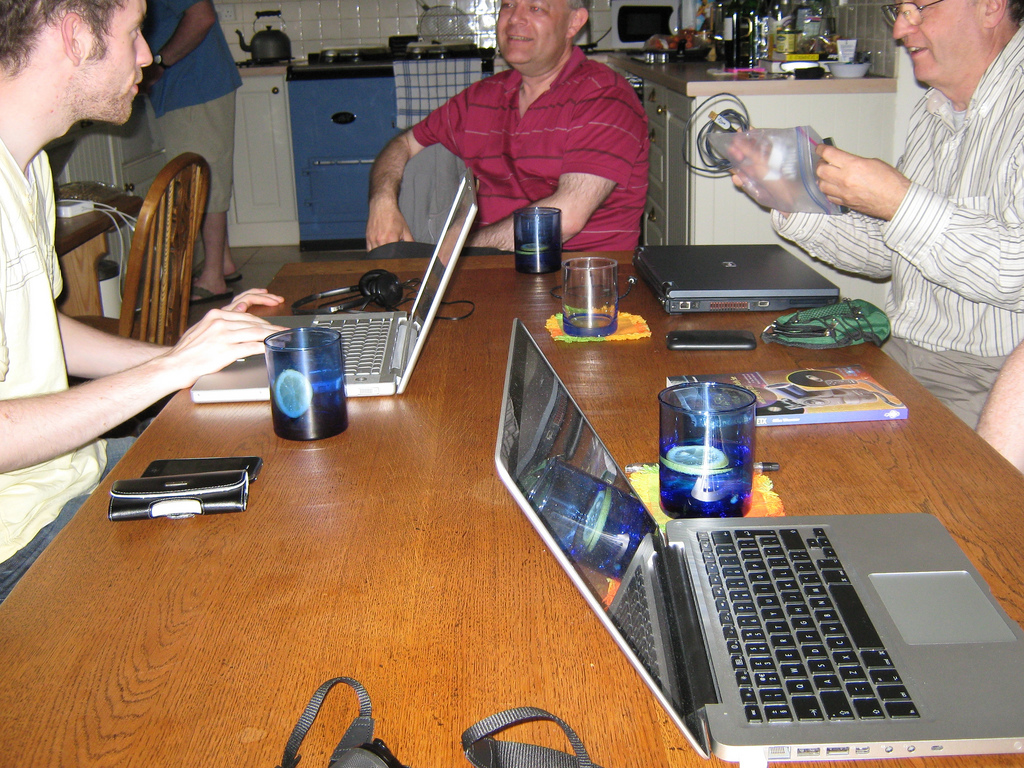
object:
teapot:
[227, 13, 306, 77]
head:
[2, 2, 152, 124]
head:
[496, 2, 592, 67]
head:
[889, 0, 1021, 84]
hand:
[169, 307, 290, 389]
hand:
[206, 284, 283, 314]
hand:
[808, 138, 906, 221]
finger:
[238, 343, 268, 356]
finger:
[246, 289, 282, 311]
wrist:
[154, 349, 206, 389]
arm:
[2, 354, 180, 473]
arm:
[57, 310, 178, 379]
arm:
[364, 95, 470, 250]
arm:
[465, 91, 637, 251]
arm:
[884, 130, 1019, 308]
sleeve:
[882, 178, 1021, 315]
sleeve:
[559, 92, 620, 187]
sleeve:
[408, 85, 482, 149]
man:
[2, 0, 297, 599]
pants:
[879, 331, 1010, 430]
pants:
[2, 495, 95, 597]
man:
[729, 2, 1020, 434]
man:
[367, 2, 654, 252]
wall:
[217, 2, 931, 167]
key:
[762, 685, 782, 702]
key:
[889, 699, 921, 719]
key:
[821, 688, 856, 721]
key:
[791, 694, 823, 724]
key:
[781, 528, 808, 552]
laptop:
[636, 245, 838, 316]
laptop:
[191, 170, 479, 406]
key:
[750, 656, 770, 670]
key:
[748, 642, 775, 655]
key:
[744, 625, 768, 642]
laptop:
[492, 318, 1020, 761]